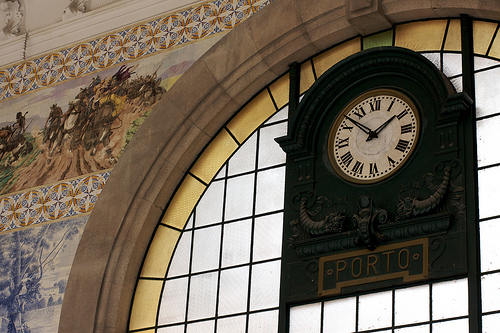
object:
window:
[66, 1, 500, 332]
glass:
[227, 91, 274, 139]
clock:
[319, 83, 429, 187]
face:
[347, 110, 404, 164]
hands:
[363, 114, 399, 142]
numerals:
[369, 100, 382, 113]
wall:
[2, 3, 201, 332]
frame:
[274, 43, 479, 305]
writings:
[335, 248, 410, 281]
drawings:
[47, 58, 165, 166]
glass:
[225, 171, 257, 222]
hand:
[345, 114, 378, 142]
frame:
[54, 53, 235, 332]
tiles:
[221, 217, 254, 269]